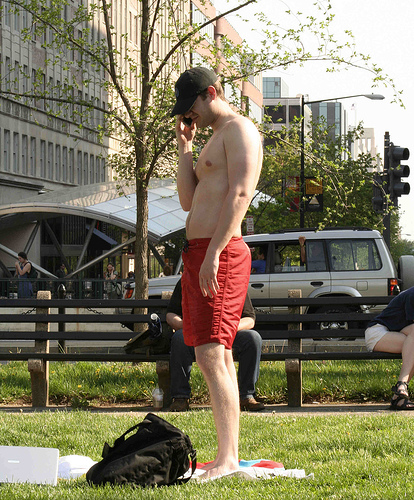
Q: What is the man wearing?
A: Shorts.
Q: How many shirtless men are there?
A: One.